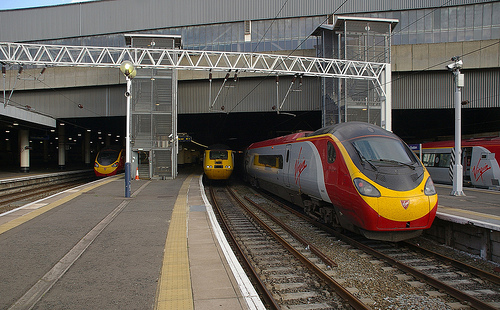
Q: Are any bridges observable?
A: Yes, there is a bridge.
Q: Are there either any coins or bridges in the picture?
A: Yes, there is a bridge.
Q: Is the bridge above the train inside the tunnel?
A: Yes, the bridge is above the train.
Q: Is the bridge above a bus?
A: No, the bridge is above the train.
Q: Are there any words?
A: Yes, there are words.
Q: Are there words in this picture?
A: Yes, there are words.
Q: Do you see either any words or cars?
A: Yes, there are words.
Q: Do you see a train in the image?
A: Yes, there is a train.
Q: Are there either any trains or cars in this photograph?
A: Yes, there is a train.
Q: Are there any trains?
A: Yes, there is a train.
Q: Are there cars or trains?
A: Yes, there is a train.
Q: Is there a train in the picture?
A: Yes, there is a train.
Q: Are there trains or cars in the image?
A: Yes, there is a train.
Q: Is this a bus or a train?
A: This is a train.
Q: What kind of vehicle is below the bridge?
A: The vehicle is a train.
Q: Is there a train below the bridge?
A: Yes, there is a train below the bridge.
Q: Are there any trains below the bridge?
A: Yes, there is a train below the bridge.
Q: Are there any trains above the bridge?
A: No, the train is below the bridge.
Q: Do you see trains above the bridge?
A: No, the train is below the bridge.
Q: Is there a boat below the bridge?
A: No, there is a train below the bridge.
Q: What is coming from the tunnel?
A: The train is coming from the tunnel.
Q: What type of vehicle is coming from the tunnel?
A: The vehicle is a train.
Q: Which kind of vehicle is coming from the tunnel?
A: The vehicle is a train.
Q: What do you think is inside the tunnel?
A: The train is inside the tunnel.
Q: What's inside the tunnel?
A: The train is inside the tunnel.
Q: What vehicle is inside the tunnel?
A: The vehicle is a train.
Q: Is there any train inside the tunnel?
A: Yes, there is a train inside the tunnel.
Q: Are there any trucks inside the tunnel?
A: No, there is a train inside the tunnel.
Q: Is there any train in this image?
A: Yes, there is a train.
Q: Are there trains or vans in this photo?
A: Yes, there is a train.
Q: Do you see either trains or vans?
A: Yes, there is a train.